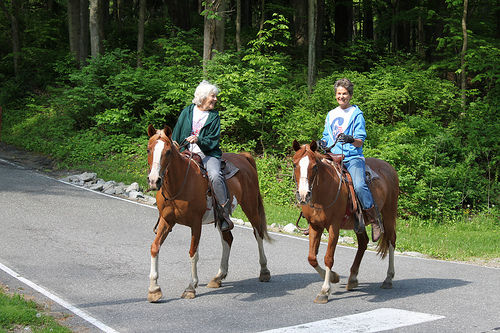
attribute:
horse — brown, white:
[130, 124, 286, 302]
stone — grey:
[66, 167, 145, 212]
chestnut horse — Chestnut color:
[146, 123, 277, 302]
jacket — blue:
[319, 104, 368, 161]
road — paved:
[0, 147, 499, 327]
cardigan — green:
[168, 102, 226, 157]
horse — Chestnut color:
[128, 164, 305, 239]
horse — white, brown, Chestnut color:
[291, 138, 398, 303]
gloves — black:
[335, 132, 356, 145]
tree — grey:
[303, 3, 320, 88]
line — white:
[2, 261, 119, 326]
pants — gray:
[193, 153, 226, 210]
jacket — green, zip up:
[179, 111, 227, 151]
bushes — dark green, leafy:
[75, 75, 167, 125]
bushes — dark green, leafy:
[402, 82, 493, 209]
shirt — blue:
[321, 107, 365, 157]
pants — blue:
[338, 153, 372, 210]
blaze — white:
[145, 137, 166, 180]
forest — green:
[1, 0, 498, 264]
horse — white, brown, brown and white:
[145, 123, 275, 301]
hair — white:
[192, 80, 219, 108]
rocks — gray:
[59, 170, 158, 206]